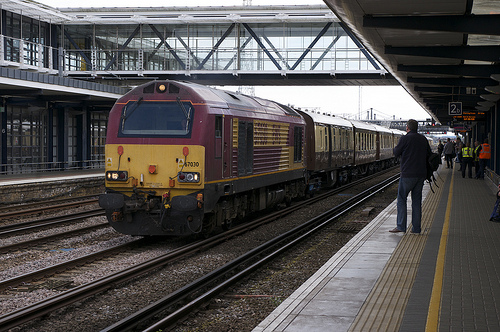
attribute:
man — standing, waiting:
[392, 120, 442, 235]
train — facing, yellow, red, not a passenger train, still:
[98, 78, 459, 244]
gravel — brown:
[15, 237, 288, 310]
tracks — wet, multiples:
[1, 140, 408, 331]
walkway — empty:
[59, 7, 389, 85]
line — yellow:
[432, 160, 459, 330]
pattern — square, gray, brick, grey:
[456, 208, 498, 281]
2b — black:
[448, 102, 464, 115]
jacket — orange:
[478, 140, 493, 162]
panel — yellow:
[106, 144, 207, 197]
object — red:
[145, 165, 161, 176]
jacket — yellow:
[460, 144, 473, 162]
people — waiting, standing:
[385, 124, 493, 236]